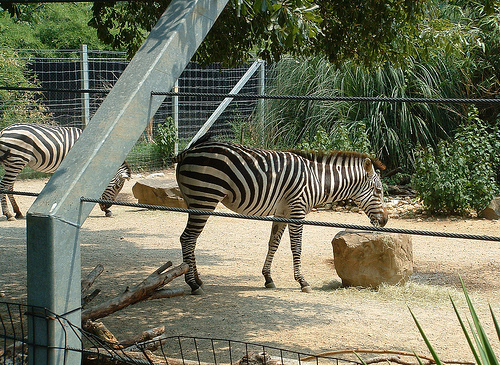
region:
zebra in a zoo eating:
[176, 141, 402, 297]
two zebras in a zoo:
[6, 52, 396, 294]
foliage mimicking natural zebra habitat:
[269, 52, 499, 183]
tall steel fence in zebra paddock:
[12, 50, 267, 133]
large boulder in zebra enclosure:
[133, 179, 191, 214]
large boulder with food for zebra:
[328, 227, 456, 306]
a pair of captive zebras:
[4, 102, 389, 291]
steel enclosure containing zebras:
[0, 35, 496, 363]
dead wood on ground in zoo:
[80, 260, 180, 342]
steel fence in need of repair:
[5, 307, 310, 359]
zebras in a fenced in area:
[6, 58, 481, 312]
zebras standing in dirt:
[22, 57, 434, 359]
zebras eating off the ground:
[37, 65, 485, 311]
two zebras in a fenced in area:
[7, 71, 492, 306]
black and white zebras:
[17, 44, 402, 332]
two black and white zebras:
[15, 60, 412, 310]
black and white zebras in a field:
[7, 73, 429, 332]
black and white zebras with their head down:
[18, 69, 461, 359]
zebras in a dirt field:
[25, 71, 433, 359]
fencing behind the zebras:
[34, 50, 271, 152]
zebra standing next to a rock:
[162, 137, 403, 293]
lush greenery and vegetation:
[273, 43, 493, 142]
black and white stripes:
[190, 146, 276, 206]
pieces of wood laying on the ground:
[81, 258, 196, 357]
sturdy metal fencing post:
[28, 5, 214, 362]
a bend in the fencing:
[49, 307, 167, 363]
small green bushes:
[408, 111, 498, 221]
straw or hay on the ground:
[335, 277, 460, 302]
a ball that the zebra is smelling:
[97, 206, 122, 226]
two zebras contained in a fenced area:
[2, 122, 390, 292]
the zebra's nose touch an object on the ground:
[0, 121, 132, 220]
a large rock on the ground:
[334, 228, 414, 290]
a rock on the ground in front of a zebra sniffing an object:
[132, 178, 184, 211]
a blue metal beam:
[27, 40, 204, 364]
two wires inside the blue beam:
[0, 82, 498, 239]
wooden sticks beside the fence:
[82, 256, 171, 347]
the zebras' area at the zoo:
[2, 1, 499, 361]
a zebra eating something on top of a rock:
[165, 140, 390, 294]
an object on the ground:
[101, 209, 118, 218]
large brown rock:
[332, 223, 413, 289]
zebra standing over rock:
[166, 143, 386, 292]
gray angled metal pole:
[22, 0, 232, 363]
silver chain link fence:
[0, 45, 275, 168]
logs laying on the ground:
[82, 257, 188, 350]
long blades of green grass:
[406, 268, 496, 363]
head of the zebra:
[352, 153, 388, 226]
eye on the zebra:
[372, 185, 383, 196]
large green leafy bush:
[420, 103, 498, 218]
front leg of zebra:
[287, 208, 311, 294]